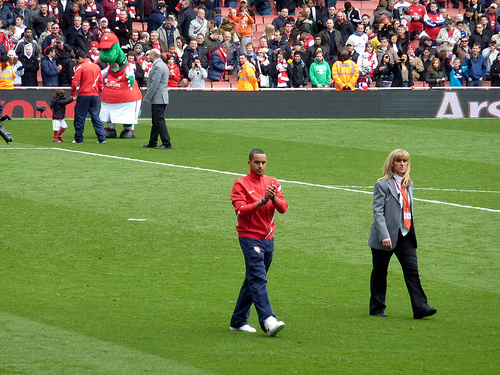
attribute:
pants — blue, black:
[71, 102, 101, 123]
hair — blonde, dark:
[385, 148, 401, 160]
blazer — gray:
[375, 192, 392, 207]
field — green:
[296, 123, 338, 143]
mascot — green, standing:
[96, 28, 144, 135]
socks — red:
[52, 131, 63, 135]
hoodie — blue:
[54, 111, 62, 116]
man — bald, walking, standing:
[229, 138, 296, 329]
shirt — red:
[260, 217, 261, 219]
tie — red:
[404, 196, 415, 206]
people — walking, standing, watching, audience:
[265, 36, 325, 74]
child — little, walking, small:
[42, 86, 73, 141]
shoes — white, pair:
[272, 318, 282, 330]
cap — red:
[97, 30, 120, 48]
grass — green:
[43, 231, 58, 240]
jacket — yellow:
[337, 65, 357, 79]